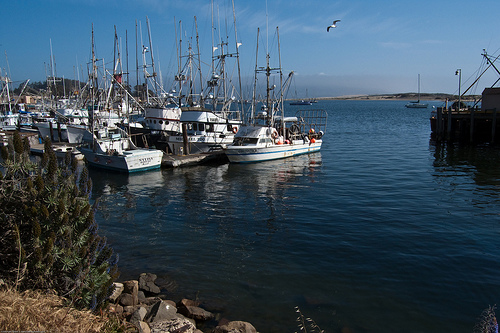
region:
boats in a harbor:
[8, 8, 491, 268]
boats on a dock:
[9, 8, 498, 238]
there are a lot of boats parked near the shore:
[0, 4, 337, 184]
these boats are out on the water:
[289, 94, 431, 114]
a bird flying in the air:
[324, 17, 348, 35]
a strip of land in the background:
[322, 81, 477, 108]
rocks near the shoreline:
[102, 264, 259, 331]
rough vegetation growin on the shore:
[5, 147, 114, 302]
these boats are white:
[35, 87, 335, 187]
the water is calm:
[184, 170, 491, 321]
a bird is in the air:
[291, 7, 348, 42]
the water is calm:
[226, 234, 428, 291]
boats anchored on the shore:
[17, 8, 298, 181]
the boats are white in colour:
[26, 15, 350, 162]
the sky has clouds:
[303, 18, 347, 86]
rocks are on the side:
[88, 287, 205, 324]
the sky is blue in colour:
[18, 8, 55, 60]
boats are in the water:
[407, 87, 420, 107]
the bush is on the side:
[1, 193, 108, 260]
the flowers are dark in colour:
[16, 155, 91, 278]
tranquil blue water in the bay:
[251, 172, 402, 237]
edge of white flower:
[273, 300, 331, 325]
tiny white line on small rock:
[163, 299, 176, 312]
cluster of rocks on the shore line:
[91, 273, 182, 322]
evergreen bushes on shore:
[18, 142, 105, 287]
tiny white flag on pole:
[223, 32, 248, 52]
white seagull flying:
[316, 16, 346, 33]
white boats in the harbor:
[38, 28, 344, 225]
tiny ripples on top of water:
[243, 189, 328, 210]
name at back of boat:
[118, 149, 172, 166]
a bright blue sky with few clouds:
[1, 0, 498, 92]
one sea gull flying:
[322, 12, 342, 36]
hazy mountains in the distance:
[168, 69, 496, 99]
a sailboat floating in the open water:
[400, 71, 430, 111]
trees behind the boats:
[11, 71, 161, 100]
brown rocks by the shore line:
[103, 270, 258, 330]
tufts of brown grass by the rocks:
[0, 285, 135, 330]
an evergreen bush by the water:
[1, 121, 118, 306]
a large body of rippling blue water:
[8, 98, 498, 331]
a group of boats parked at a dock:
[3, 5, 337, 180]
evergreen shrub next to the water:
[0, 130, 122, 312]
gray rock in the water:
[180, 295, 214, 320]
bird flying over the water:
[324, 18, 341, 31]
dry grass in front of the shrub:
[1, 283, 120, 331]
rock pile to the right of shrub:
[98, 270, 258, 332]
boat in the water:
[222, 23, 323, 163]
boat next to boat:
[168, 13, 269, 158]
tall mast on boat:
[249, 25, 295, 140]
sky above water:
[1, 2, 499, 107]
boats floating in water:
[0, 13, 325, 174]